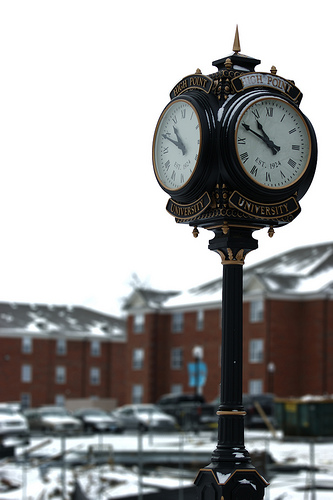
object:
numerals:
[237, 134, 246, 147]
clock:
[234, 97, 309, 187]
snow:
[175, 290, 208, 304]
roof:
[281, 243, 333, 296]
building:
[1, 240, 332, 395]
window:
[169, 311, 185, 336]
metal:
[218, 263, 244, 451]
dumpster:
[281, 390, 333, 442]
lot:
[0, 347, 196, 490]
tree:
[78, 452, 103, 475]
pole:
[218, 220, 246, 471]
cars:
[125, 404, 173, 432]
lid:
[270, 389, 332, 402]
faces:
[236, 101, 308, 188]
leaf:
[217, 246, 246, 264]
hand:
[242, 120, 281, 153]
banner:
[187, 355, 208, 388]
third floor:
[129, 296, 147, 401]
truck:
[29, 392, 80, 437]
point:
[231, 23, 242, 56]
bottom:
[204, 232, 262, 265]